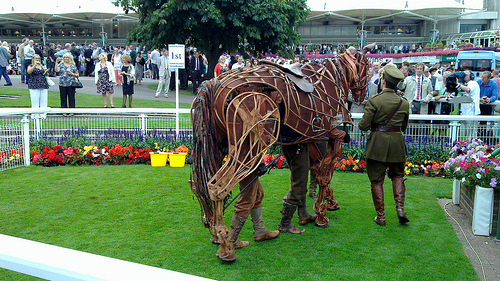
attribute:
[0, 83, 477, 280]
grass — green, visibile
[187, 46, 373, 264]
horse — metal, sculpture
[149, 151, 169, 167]
bucket — yellow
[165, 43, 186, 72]
sign — green, white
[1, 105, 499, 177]
fence — white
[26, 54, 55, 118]
woman — photographing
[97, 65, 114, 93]
dress — floral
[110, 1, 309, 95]
tree — green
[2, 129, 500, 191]
flowers — colorful, group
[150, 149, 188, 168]
buckets — yellow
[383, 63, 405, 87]
hat — green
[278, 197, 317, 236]
boots — brown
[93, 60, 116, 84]
sweater — white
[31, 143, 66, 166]
flowers — red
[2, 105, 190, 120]
rail — white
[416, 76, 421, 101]
tie — red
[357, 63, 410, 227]
uniform — military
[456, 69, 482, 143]
man — filming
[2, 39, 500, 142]
people — crowd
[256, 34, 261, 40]
leaf — green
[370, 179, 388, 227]
boot — brown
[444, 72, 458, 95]
camera — large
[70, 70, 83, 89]
purse — black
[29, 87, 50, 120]
pants — white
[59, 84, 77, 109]
pants — black